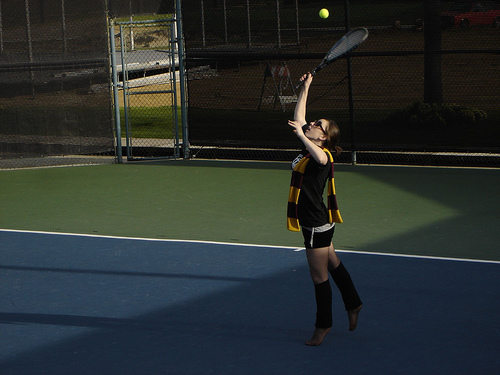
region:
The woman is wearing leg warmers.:
[306, 259, 379, 338]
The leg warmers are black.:
[281, 255, 383, 333]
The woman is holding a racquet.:
[268, 21, 383, 95]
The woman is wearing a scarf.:
[281, 131, 358, 235]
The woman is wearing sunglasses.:
[308, 113, 329, 140]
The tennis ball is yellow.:
[311, 5, 340, 24]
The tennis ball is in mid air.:
[308, 7, 339, 27]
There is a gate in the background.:
[101, 12, 209, 168]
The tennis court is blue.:
[4, 220, 494, 370]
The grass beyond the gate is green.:
[116, 104, 192, 146]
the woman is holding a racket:
[275, 4, 391, 314]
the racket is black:
[300, 20, 421, 120]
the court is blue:
[102, 241, 159, 321]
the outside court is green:
[106, 173, 190, 217]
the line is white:
[166, 230, 212, 255]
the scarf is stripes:
[277, 144, 309, 229]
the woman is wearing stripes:
[262, 79, 347, 244]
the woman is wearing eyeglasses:
[296, 101, 328, 148]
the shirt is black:
[282, 134, 342, 233]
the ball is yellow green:
[313, 9, 344, 28]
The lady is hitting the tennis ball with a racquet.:
[233, 8, 423, 333]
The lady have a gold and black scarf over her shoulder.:
[288, 140, 345, 237]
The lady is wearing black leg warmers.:
[306, 280, 351, 323]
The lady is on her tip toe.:
[283, 228, 380, 358]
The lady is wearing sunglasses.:
[286, 113, 339, 149]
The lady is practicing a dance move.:
[293, 64, 375, 359]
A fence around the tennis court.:
[101, 17, 498, 165]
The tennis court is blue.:
[59, 243, 401, 342]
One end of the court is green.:
[89, 163, 454, 243]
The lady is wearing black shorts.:
[303, 219, 356, 262]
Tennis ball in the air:
[316, 5, 333, 23]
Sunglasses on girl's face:
[312, 118, 332, 138]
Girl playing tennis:
[281, 72, 368, 349]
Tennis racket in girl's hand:
[287, 22, 388, 93]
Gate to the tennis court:
[108, 18, 195, 162]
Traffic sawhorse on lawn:
[256, 57, 296, 116]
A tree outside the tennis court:
[406, 0, 475, 102]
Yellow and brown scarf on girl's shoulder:
[283, 146, 356, 228]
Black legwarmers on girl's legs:
[308, 258, 370, 335]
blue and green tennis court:
[0, 156, 499, 373]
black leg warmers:
[309, 278, 406, 340]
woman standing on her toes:
[279, 72, 405, 372]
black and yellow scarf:
[288, 141, 363, 248]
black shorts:
[296, 223, 363, 249]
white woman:
[280, 66, 357, 277]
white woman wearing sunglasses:
[278, 107, 392, 220]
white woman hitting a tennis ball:
[286, 7, 427, 253]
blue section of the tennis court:
[51, 237, 345, 367]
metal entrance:
[115, 21, 180, 136]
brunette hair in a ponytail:
[318, 123, 360, 171]